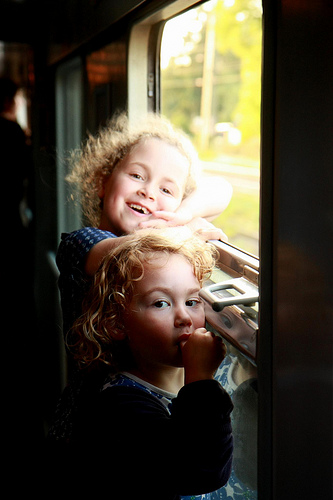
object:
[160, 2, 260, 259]
glass